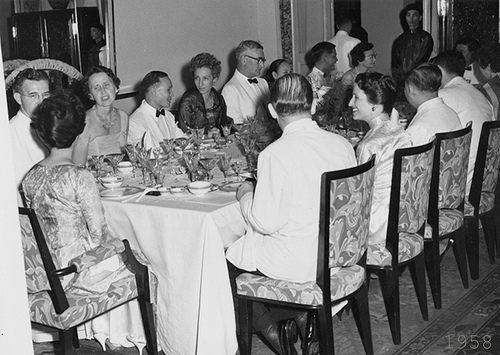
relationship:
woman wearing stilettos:
[345, 77, 401, 240] [323, 305, 356, 328]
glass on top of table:
[187, 146, 231, 180] [179, 203, 230, 234]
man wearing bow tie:
[141, 60, 176, 139] [147, 102, 169, 116]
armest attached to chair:
[35, 252, 152, 261] [326, 168, 370, 262]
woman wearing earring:
[345, 77, 401, 240] [369, 103, 379, 116]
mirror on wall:
[18, 17, 89, 56] [145, 9, 225, 31]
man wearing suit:
[141, 60, 176, 139] [222, 84, 257, 117]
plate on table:
[184, 172, 219, 190] [179, 203, 230, 234]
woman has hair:
[345, 77, 401, 240] [362, 78, 401, 113]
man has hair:
[141, 60, 176, 139] [362, 78, 401, 113]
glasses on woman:
[241, 54, 265, 63] [345, 77, 401, 240]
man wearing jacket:
[141, 60, 176, 139] [231, 145, 356, 289]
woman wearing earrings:
[345, 77, 401, 240] [359, 93, 379, 116]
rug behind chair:
[435, 314, 483, 346] [326, 168, 370, 262]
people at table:
[21, 41, 436, 227] [179, 203, 230, 234]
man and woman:
[141, 60, 176, 139] [345, 77, 401, 240]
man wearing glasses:
[141, 60, 176, 139] [241, 54, 265, 63]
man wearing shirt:
[141, 60, 176, 139] [119, 107, 201, 139]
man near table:
[141, 60, 176, 139] [179, 203, 230, 234]